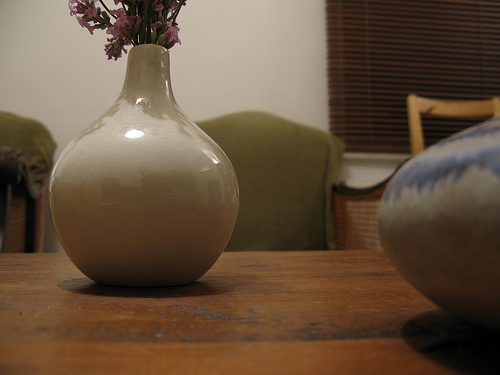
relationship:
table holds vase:
[6, 240, 494, 366] [48, 36, 240, 292]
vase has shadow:
[48, 36, 240, 292] [56, 274, 226, 300]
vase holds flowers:
[48, 36, 240, 292] [69, 3, 185, 61]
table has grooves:
[6, 240, 494, 366] [43, 310, 236, 352]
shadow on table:
[56, 274, 226, 300] [17, 234, 485, 373]